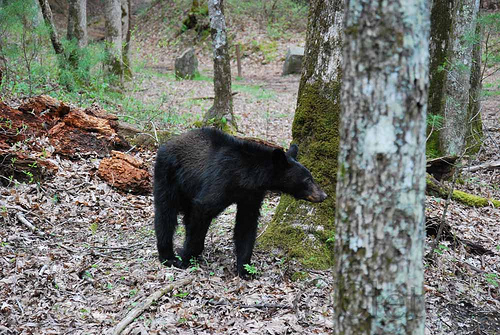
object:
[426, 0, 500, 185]
plant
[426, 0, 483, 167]
tree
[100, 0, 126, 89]
tree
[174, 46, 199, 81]
stump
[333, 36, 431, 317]
bark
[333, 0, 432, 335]
tree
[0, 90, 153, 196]
tree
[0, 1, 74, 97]
plants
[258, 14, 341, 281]
moss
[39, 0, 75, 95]
tree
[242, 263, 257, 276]
plant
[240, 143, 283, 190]
neck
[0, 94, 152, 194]
brown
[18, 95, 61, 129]
wood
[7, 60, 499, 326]
ground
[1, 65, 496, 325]
dirt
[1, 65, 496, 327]
branches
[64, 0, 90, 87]
trees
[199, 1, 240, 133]
tree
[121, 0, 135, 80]
tree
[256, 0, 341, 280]
plant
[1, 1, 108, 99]
young trees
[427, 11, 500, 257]
tree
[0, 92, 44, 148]
wood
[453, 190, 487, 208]
plant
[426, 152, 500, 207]
log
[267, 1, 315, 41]
tree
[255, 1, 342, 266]
trunk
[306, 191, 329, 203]
mouth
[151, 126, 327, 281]
animal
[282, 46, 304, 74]
rock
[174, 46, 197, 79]
rock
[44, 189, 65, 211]
twig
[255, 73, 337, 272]
lichens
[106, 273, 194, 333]
stick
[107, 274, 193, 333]
debris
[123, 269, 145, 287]
debris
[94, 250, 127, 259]
debris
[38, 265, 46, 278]
debris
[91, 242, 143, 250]
debris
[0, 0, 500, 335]
leaves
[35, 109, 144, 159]
wooden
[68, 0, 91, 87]
wood